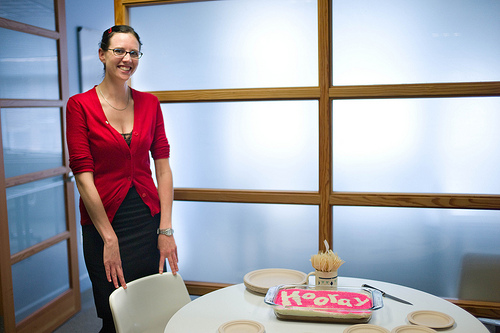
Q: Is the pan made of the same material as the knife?
A: No, the pan is made of glass and the knife is made of metal.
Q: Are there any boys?
A: No, there are no boys.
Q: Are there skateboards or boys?
A: No, there are no boys or skateboards.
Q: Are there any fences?
A: No, there are no fences.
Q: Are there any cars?
A: No, there are no cars.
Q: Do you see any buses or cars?
A: No, there are no cars or buses.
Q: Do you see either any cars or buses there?
A: No, there are no cars or buses.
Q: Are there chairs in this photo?
A: Yes, there is a chair.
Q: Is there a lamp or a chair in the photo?
A: Yes, there is a chair.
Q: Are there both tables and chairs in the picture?
A: Yes, there are both a chair and a table.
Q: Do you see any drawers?
A: No, there are no drawers.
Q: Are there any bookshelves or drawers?
A: No, there are no drawers or bookshelves.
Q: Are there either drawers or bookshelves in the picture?
A: No, there are no drawers or bookshelves.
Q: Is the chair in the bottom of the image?
A: Yes, the chair is in the bottom of the image.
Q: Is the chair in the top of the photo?
A: No, the chair is in the bottom of the image.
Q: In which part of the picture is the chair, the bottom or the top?
A: The chair is in the bottom of the image.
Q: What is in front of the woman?
A: The chair is in front of the woman.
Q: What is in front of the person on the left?
A: The chair is in front of the woman.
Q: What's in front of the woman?
A: The chair is in front of the woman.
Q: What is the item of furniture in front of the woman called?
A: The piece of furniture is a chair.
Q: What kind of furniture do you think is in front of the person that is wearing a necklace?
A: The piece of furniture is a chair.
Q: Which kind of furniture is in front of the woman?
A: The piece of furniture is a chair.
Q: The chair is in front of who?
A: The chair is in front of the woman.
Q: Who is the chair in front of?
A: The chair is in front of the woman.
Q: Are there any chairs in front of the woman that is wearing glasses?
A: Yes, there is a chair in front of the woman.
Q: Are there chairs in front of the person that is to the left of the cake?
A: Yes, there is a chair in front of the woman.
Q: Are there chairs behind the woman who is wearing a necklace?
A: No, the chair is in front of the woman.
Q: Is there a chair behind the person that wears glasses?
A: No, the chair is in front of the woman.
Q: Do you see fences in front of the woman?
A: No, there is a chair in front of the woman.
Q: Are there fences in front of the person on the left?
A: No, there is a chair in front of the woman.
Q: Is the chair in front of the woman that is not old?
A: Yes, the chair is in front of the woman.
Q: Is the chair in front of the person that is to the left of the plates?
A: Yes, the chair is in front of the woman.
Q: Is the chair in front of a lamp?
A: No, the chair is in front of the woman.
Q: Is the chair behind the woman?
A: No, the chair is in front of the woman.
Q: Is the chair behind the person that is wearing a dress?
A: No, the chair is in front of the woman.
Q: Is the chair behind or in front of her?
A: The chair is in front of the woman.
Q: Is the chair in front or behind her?
A: The chair is in front of the woman.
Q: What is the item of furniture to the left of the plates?
A: The piece of furniture is a chair.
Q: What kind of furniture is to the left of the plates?
A: The piece of furniture is a chair.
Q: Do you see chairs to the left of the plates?
A: Yes, there is a chair to the left of the plates.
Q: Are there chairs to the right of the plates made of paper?
A: No, the chair is to the left of the plates.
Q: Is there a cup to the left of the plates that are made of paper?
A: No, there is a chair to the left of the plates.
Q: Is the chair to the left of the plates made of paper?
A: Yes, the chair is to the left of the plates.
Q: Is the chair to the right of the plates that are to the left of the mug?
A: No, the chair is to the left of the plates.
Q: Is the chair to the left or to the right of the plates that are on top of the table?
A: The chair is to the left of the plates.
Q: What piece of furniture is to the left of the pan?
A: The piece of furniture is a chair.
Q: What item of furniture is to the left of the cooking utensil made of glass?
A: The piece of furniture is a chair.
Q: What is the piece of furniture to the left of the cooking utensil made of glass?
A: The piece of furniture is a chair.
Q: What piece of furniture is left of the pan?
A: The piece of furniture is a chair.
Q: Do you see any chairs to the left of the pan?
A: Yes, there is a chair to the left of the pan.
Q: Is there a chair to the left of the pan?
A: Yes, there is a chair to the left of the pan.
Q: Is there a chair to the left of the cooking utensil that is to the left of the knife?
A: Yes, there is a chair to the left of the pan.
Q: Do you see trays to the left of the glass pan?
A: No, there is a chair to the left of the pan.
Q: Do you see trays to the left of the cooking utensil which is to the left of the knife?
A: No, there is a chair to the left of the pan.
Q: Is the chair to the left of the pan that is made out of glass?
A: Yes, the chair is to the left of the pan.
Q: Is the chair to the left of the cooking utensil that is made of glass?
A: Yes, the chair is to the left of the pan.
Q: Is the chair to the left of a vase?
A: No, the chair is to the left of the pan.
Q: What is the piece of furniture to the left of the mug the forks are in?
A: The piece of furniture is a chair.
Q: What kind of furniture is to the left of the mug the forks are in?
A: The piece of furniture is a chair.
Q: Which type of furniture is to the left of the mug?
A: The piece of furniture is a chair.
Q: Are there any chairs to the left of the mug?
A: Yes, there is a chair to the left of the mug.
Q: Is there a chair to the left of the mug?
A: Yes, there is a chair to the left of the mug.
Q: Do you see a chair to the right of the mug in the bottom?
A: No, the chair is to the left of the mug.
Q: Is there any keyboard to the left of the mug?
A: No, there is a chair to the left of the mug.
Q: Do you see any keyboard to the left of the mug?
A: No, there is a chair to the left of the mug.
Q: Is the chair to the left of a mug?
A: Yes, the chair is to the left of a mug.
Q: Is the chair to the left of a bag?
A: No, the chair is to the left of a mug.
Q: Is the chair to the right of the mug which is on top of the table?
A: No, the chair is to the left of the mug.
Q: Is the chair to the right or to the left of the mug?
A: The chair is to the left of the mug.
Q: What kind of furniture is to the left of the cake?
A: The piece of furniture is a chair.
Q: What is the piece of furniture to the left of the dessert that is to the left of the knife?
A: The piece of furniture is a chair.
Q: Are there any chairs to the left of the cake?
A: Yes, there is a chair to the left of the cake.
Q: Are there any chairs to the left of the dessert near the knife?
A: Yes, there is a chair to the left of the cake.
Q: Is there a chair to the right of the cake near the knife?
A: No, the chair is to the left of the cake.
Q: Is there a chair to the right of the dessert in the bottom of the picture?
A: No, the chair is to the left of the cake.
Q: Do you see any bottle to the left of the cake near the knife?
A: No, there is a chair to the left of the cake.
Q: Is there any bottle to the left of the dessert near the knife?
A: No, there is a chair to the left of the cake.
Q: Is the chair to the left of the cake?
A: Yes, the chair is to the left of the cake.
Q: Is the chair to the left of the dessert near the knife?
A: Yes, the chair is to the left of the cake.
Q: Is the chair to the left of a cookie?
A: No, the chair is to the left of the cake.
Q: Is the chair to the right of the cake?
A: No, the chair is to the left of the cake.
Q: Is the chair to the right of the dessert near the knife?
A: No, the chair is to the left of the cake.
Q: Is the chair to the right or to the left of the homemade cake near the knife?
A: The chair is to the left of the cake.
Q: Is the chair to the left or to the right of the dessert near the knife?
A: The chair is to the left of the cake.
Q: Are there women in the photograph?
A: Yes, there is a woman.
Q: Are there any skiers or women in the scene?
A: Yes, there is a woman.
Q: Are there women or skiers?
A: Yes, there is a woman.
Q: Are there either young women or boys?
A: Yes, there is a young woman.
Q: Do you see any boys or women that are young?
A: Yes, the woman is young.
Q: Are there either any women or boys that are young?
A: Yes, the woman is young.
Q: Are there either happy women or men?
A: Yes, there is a happy woman.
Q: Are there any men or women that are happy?
A: Yes, the woman is happy.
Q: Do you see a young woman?
A: Yes, there is a young woman.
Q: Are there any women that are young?
A: Yes, there is a woman that is young.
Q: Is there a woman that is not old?
A: Yes, there is an young woman.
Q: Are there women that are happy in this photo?
A: Yes, there is a happy woman.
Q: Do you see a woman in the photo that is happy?
A: Yes, there is a woman that is happy.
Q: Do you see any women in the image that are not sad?
A: Yes, there is a happy woman.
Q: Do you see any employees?
A: No, there are no employees.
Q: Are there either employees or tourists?
A: No, there are no employees or tourists.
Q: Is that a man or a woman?
A: That is a woman.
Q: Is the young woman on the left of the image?
A: Yes, the woman is on the left of the image.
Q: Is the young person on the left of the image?
A: Yes, the woman is on the left of the image.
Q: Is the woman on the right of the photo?
A: No, the woman is on the left of the image.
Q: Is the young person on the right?
A: No, the woman is on the left of the image.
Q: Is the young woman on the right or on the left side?
A: The woman is on the left of the image.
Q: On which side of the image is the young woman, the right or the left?
A: The woman is on the left of the image.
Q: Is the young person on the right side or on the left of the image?
A: The woman is on the left of the image.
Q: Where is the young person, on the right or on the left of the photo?
A: The woman is on the left of the image.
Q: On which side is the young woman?
A: The woman is on the left of the image.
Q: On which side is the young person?
A: The woman is on the left of the image.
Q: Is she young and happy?
A: Yes, the woman is young and happy.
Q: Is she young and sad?
A: No, the woman is young but happy.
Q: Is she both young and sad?
A: No, the woman is young but happy.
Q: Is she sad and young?
A: No, the woman is young but happy.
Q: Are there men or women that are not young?
A: No, there is a woman but she is young.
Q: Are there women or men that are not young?
A: No, there is a woman but she is young.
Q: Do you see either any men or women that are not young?
A: No, there is a woman but she is young.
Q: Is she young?
A: Yes, the woman is young.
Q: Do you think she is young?
A: Yes, the woman is young.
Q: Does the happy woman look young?
A: Yes, the woman is young.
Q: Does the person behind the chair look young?
A: Yes, the woman is young.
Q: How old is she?
A: The woman is young.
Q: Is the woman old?
A: No, the woman is young.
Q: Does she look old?
A: No, the woman is young.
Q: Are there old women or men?
A: No, there is a woman but she is young.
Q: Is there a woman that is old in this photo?
A: No, there is a woman but she is young.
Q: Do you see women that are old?
A: No, there is a woman but she is young.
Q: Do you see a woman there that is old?
A: No, there is a woman but she is young.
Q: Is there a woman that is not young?
A: No, there is a woman but she is young.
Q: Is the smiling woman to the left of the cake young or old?
A: The woman is young.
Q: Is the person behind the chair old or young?
A: The woman is young.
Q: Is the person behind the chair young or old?
A: The woman is young.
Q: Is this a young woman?
A: Yes, this is a young woman.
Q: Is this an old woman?
A: No, this is a young woman.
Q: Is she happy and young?
A: Yes, the woman is happy and young.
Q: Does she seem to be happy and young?
A: Yes, the woman is happy and young.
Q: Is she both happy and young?
A: Yes, the woman is happy and young.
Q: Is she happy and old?
A: No, the woman is happy but young.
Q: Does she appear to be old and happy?
A: No, the woman is happy but young.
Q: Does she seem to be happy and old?
A: No, the woman is happy but young.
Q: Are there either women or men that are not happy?
A: No, there is a woman but she is happy.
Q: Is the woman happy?
A: Yes, the woman is happy.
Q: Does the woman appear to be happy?
A: Yes, the woman is happy.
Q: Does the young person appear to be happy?
A: Yes, the woman is happy.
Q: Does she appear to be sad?
A: No, the woman is happy.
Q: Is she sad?
A: No, the woman is happy.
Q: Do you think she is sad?
A: No, the woman is happy.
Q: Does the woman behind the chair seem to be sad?
A: No, the woman is happy.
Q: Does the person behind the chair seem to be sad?
A: No, the woman is happy.